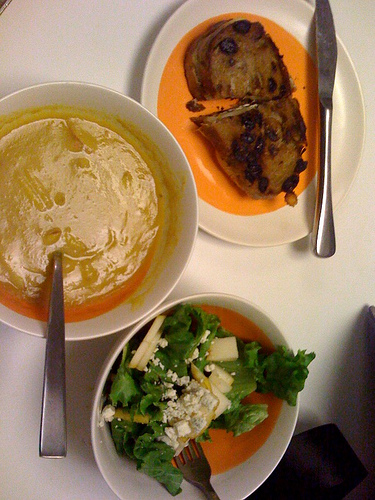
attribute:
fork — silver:
[169, 433, 222, 498]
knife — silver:
[312, 1, 338, 257]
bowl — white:
[89, 289, 303, 499]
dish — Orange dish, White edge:
[4, 79, 198, 340]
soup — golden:
[4, 66, 170, 326]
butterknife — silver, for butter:
[299, 3, 341, 264]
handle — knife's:
[312, 101, 339, 258]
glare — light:
[315, 109, 330, 254]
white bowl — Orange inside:
[91, 289, 313, 498]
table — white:
[4, 1, 369, 493]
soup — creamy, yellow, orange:
[1, 103, 186, 323]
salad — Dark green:
[98, 302, 315, 494]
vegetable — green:
[90, 323, 328, 479]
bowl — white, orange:
[0, 84, 210, 345]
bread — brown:
[192, 20, 306, 203]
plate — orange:
[138, 0, 365, 243]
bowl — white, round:
[7, 73, 204, 346]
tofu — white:
[125, 305, 176, 384]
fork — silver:
[181, 448, 241, 498]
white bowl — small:
[216, 427, 290, 498]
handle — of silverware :
[40, 257, 67, 459]